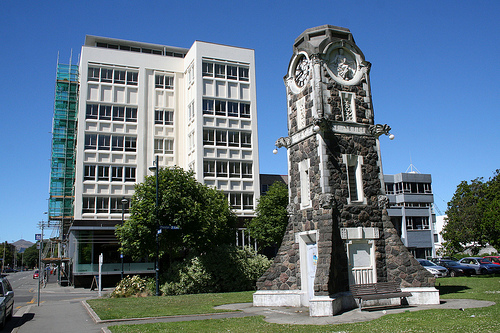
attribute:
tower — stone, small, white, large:
[241, 21, 437, 308]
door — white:
[295, 231, 322, 313]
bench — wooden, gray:
[350, 281, 411, 306]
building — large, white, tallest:
[53, 34, 463, 275]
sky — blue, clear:
[11, 4, 489, 234]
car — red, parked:
[34, 264, 43, 281]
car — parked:
[3, 269, 15, 327]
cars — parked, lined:
[420, 248, 498, 275]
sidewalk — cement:
[8, 284, 491, 332]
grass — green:
[105, 273, 490, 332]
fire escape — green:
[54, 71, 71, 287]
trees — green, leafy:
[440, 173, 497, 260]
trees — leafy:
[120, 167, 284, 248]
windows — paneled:
[88, 60, 235, 213]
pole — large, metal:
[151, 159, 161, 304]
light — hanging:
[271, 128, 291, 157]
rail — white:
[345, 269, 376, 286]